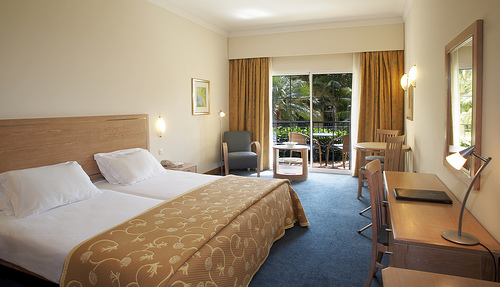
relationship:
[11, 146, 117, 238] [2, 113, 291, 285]
pillow on bed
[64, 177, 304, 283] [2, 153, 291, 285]
blanket on bed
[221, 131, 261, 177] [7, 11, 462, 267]
chair in room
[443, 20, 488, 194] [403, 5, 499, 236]
mirror on wall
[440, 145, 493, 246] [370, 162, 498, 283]
lamp on table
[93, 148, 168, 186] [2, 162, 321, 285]
pillow on bed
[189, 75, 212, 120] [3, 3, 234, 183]
frame on wall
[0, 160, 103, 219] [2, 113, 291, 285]
pillow on bed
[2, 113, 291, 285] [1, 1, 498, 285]
bed in room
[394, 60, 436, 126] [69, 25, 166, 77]
fixture on wall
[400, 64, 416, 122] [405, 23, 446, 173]
fixture on wall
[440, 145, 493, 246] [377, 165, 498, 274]
lamp on dresser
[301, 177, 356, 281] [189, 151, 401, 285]
carpeting on floor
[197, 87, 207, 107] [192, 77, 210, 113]
picture in frame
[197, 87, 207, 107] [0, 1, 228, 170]
picture on wall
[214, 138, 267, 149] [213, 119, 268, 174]
arms are on chair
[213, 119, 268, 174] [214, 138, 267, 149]
chair with arms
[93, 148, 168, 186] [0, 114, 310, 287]
pillow on bed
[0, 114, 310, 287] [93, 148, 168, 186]
bed with pillow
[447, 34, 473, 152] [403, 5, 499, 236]
mirror on wall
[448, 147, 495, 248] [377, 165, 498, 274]
lamp on dresser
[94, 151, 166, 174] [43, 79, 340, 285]
pillow on bed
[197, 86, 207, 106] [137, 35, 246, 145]
picture on wall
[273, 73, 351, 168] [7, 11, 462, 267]
window in room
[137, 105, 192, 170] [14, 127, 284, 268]
lamp beside bed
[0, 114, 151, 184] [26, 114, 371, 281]
head board of bed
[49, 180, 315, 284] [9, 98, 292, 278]
comforter on bed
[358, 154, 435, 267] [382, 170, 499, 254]
chair in front of table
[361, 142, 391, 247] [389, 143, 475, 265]
chair in front of table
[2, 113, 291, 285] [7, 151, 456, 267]
bed in foreground